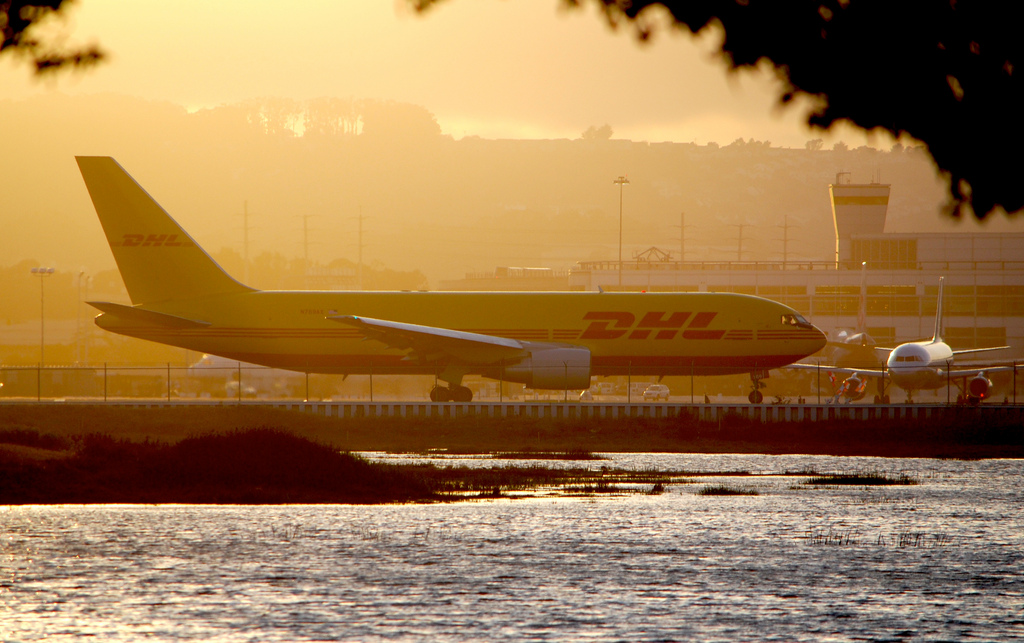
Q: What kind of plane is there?
A: Commercial plane.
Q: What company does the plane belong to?
A: DHL.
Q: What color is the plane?
A: Yellow.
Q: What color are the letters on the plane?
A: Red.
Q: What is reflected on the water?
A: Sunlight.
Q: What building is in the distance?
A: Airport.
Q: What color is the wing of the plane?
A: White.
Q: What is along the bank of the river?
A: Grass.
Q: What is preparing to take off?
A: Another plane.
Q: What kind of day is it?
A: Gloomy.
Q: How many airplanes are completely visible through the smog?
A: 2.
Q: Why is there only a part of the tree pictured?
A: The camera focus.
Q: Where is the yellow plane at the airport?
A: Runway.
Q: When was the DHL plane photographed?
A: Early morning.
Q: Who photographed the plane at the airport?
A: A tourist.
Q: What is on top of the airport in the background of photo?
A: Traffic control tower.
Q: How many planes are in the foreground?
A: 1.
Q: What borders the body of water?
A: Grass and weeds.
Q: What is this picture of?
A: In an airport.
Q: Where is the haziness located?
A: In the sky.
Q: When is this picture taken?
A: Near the airport on water.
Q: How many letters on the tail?
A: 3.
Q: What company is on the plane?
A: DHL.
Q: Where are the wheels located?
A: Under the plane.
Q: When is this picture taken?
A: At an airport.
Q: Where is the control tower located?
A: Right corner.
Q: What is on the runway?
A: Airplanes.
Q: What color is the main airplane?
A: Yellow.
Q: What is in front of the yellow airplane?
A: A chain link fence.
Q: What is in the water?
A: Vegetation.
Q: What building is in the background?
A: An airport.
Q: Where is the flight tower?
A: In the background at the airport.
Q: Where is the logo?
A: On the airplane's fuselage.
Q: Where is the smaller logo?
A: On the tail fin.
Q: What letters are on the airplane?
A: DHL.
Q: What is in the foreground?
A: Water.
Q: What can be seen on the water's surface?
A: Ripples.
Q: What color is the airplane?
A: Yellow.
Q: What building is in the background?
A: An airport.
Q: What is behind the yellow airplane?
A: A fence.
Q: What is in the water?
A: A small island.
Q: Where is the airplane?
A: On the runway.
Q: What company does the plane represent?
A: DHL.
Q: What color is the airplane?
A: Yellow/red.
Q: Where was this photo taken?
A: Airport.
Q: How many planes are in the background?
A: 2.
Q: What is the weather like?
A: Smoggy.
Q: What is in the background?
A: Airport/airplanes.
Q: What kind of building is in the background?
A: Airport.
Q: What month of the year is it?
A: October.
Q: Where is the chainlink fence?
A: Next to the plane.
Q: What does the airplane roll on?
A: Wheels.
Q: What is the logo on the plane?
A: DHL.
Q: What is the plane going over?
A: A body of water.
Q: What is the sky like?
A: Overcast.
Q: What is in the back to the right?
A: Terminal.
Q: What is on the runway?
A: Airplane.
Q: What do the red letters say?
A: DHL.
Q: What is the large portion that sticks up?
A: Tail.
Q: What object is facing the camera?
A: Airplane.